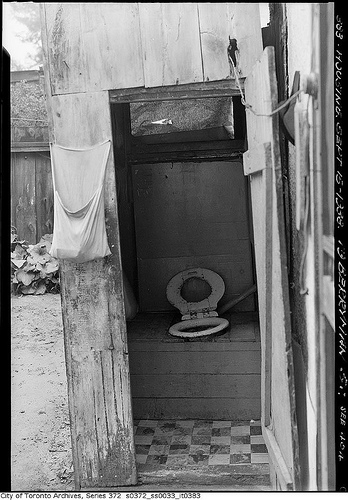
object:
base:
[142, 262, 258, 424]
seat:
[168, 315, 231, 339]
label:
[130, 93, 233, 136]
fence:
[11, 143, 57, 293]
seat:
[166, 269, 227, 340]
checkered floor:
[131, 415, 272, 470]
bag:
[45, 129, 112, 266]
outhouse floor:
[141, 341, 258, 467]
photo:
[6, 6, 327, 488]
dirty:
[111, 269, 260, 423]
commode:
[166, 266, 230, 338]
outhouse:
[39, 1, 300, 488]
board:
[48, 0, 260, 81]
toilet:
[167, 266, 228, 338]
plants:
[5, 0, 42, 72]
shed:
[66, 16, 302, 494]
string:
[228, 52, 303, 117]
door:
[240, 44, 301, 491]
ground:
[9, 286, 74, 489]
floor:
[133, 419, 294, 485]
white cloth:
[46, 133, 117, 263]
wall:
[59, 8, 142, 466]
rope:
[239, 87, 302, 118]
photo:
[0, 1, 348, 499]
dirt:
[13, 388, 68, 445]